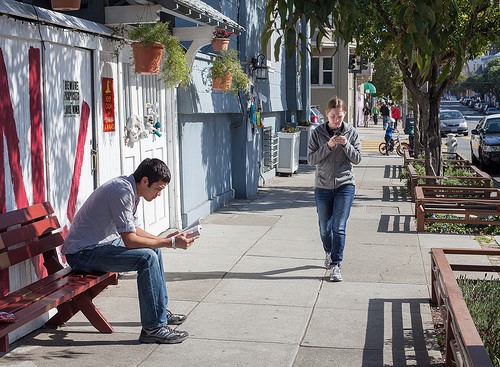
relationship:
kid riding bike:
[383, 119, 398, 154] [375, 142, 410, 159]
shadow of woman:
[161, 268, 327, 283] [319, 97, 345, 283]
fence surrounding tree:
[410, 174, 487, 186] [400, 1, 452, 174]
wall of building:
[4, 6, 87, 201] [157, 5, 241, 199]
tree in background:
[410, 48, 428, 151] [398, 55, 424, 162]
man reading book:
[62, 159, 173, 341] [172, 223, 203, 241]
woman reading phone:
[319, 97, 345, 283] [332, 132, 347, 141]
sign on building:
[94, 73, 122, 133] [95, 24, 128, 163]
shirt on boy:
[387, 126, 397, 137] [383, 119, 398, 154]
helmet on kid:
[386, 117, 397, 123] [383, 119, 398, 154]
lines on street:
[366, 137, 373, 152] [364, 127, 378, 160]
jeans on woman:
[308, 188, 344, 259] [319, 97, 345, 283]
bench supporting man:
[1, 240, 110, 356] [62, 159, 173, 341]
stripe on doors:
[15, 31, 50, 197] [4, 40, 95, 201]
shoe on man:
[129, 323, 196, 347] [62, 159, 173, 341]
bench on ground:
[1, 240, 110, 356] [0, 310, 107, 365]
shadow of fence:
[381, 211, 417, 237] [416, 186, 495, 232]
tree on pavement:
[400, 1, 452, 174] [0, 128, 500, 367]